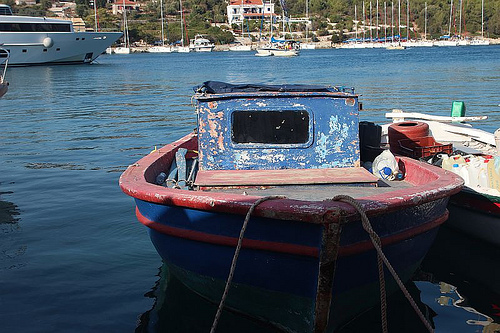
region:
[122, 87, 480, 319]
blue and red boat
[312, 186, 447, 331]
rope on the right side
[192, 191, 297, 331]
rope on the left side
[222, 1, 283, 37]
house at the end of the lake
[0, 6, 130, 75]
white yacht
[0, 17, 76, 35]
black windows in the white yacht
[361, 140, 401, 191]
bottle in the right side of the boat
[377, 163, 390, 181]
blue cover of the bottle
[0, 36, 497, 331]
large body of water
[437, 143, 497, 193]
set of bottles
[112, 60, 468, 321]
A dilapidated boat.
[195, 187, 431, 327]
Ropes.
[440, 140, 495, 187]
Plastic jugs.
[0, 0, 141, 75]
A large yacht.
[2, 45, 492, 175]
The water is calm.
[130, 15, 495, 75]
A large amount of docked boats in the distance.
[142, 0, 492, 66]
Many of the boats have masts.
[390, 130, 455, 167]
A red plastic crate.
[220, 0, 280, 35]
A large white and red building.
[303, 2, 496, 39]
A forest.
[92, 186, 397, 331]
A rope hanging over boat.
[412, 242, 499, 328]
Sludge in the water.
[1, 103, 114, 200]
Small ripples on the water.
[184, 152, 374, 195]
A brown piece of wood.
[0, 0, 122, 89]
A white yacht on water.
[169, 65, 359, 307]
A small blue and red boat.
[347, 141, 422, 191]
A little bit of trash.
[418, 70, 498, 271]
Small boat filled with stuff.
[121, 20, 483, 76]
Boats near the shore.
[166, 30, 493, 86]
Sandy beach area by water.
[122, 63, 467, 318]
red boat in the water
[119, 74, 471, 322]
Boat is old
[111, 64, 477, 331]
Paint of the boat is coming off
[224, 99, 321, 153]
Window of boat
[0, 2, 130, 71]
Yacht is white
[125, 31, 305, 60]
Boats on side of water body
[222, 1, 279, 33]
Home is white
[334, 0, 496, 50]
White boats side-by-side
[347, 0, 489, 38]
Mast of boats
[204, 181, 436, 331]
Rope on boat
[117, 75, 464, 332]
Blue and red boat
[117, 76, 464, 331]
Red and blue anchored to dock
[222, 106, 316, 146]
Window on small blue boat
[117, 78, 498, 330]
Two boats anchored to the dock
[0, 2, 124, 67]
Large white boat on the water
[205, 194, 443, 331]
Rope attached the boat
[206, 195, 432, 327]
Rope with anchor attached to dock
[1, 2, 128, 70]
White boat cruising on the river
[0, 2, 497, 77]
White luxury boat traveling on the river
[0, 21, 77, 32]
Windows on the boat